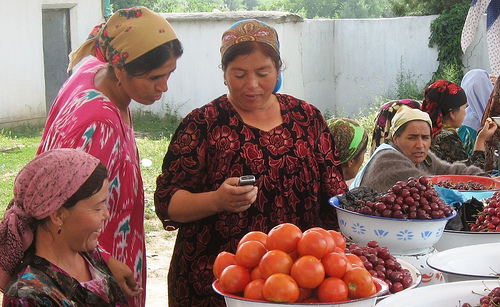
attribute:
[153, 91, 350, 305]
dress — red, floral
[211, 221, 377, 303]
tomatoes — red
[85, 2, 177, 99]
bandana — yellow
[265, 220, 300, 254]
tomato — piled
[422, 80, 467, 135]
headband — black, red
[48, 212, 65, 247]
earring — red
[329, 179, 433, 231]
bowl — white, blue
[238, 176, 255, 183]
mobile phone — black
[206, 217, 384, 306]
tomatoes — ripe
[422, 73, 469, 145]
head band — green, brown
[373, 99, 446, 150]
cover — tan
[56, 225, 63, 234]
earring — black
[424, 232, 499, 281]
bowl — empty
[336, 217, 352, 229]
designs — blue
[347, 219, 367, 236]
designs — blue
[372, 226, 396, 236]
designs — blue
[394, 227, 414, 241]
designs — blue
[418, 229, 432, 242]
designs — blue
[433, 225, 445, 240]
designs — blue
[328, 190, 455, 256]
bowl — white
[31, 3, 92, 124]
door — gray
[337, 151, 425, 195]
sweater — grey